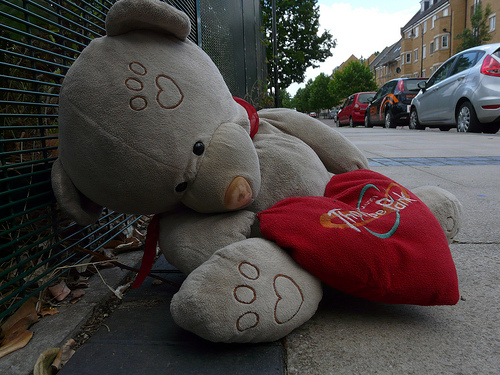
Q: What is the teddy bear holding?
A: A heart.